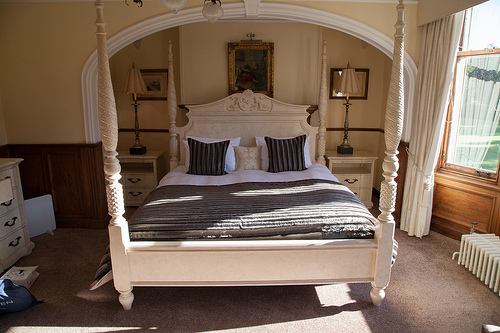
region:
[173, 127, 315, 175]
Black striped pillows on a bed.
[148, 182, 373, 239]
A black ruffled comforter.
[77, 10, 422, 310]
A cream colored bed frame.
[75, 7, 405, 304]
A four poster bed.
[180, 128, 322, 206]
Pillows stacked on a bed.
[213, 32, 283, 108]
An antique gold framed picture.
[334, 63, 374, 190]
A lamp on an end table.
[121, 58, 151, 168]
A lamp on an end table.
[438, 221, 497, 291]
A white radiator by the window.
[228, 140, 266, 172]
A tan throw pillow.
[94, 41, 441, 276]
the bed is white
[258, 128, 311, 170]
the pillows are black and white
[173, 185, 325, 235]
the blanket is gray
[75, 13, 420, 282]
the bed has four posts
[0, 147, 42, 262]
The dresser is white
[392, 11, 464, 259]
The drapes are white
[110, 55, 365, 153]
There are two lamps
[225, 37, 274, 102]
There is a picture behind the bed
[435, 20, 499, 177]
The drapes are open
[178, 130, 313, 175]
bed room bed pillows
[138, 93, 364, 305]
large king bed in bedroom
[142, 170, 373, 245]
king comforter covering mattress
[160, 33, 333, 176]
wooden headboard with design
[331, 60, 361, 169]
elegant looking tall lamps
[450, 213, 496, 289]
white smaller looking radiator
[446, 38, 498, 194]
large windows that bring in a lot of light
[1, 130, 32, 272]
bedroom dresser matches bed head and foot board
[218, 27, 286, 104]
very elegant picture on wall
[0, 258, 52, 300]
clutter on the floor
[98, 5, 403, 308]
white four poster bed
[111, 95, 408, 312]
dark bedding on white bed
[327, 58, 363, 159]
standing lamp on end table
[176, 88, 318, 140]
ornate white head board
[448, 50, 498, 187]
window with sun shining through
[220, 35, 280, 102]
painting in gold frame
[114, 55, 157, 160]
standing lamp on end table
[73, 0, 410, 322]
bedroom with symmetry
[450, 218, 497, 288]
white pipe air heater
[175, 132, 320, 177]
black and white decorative pillows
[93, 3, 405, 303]
white painted poster bed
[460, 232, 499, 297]
white radiator on floor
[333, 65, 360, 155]
lamp on end table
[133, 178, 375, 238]
grey comforter on bed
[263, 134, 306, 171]
black and white pillow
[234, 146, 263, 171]
tan pillow on bed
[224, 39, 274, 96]
picture hanging on wall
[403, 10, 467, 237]
white drapes on window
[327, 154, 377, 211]
white painted end table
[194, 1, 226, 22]
light hanging on wall